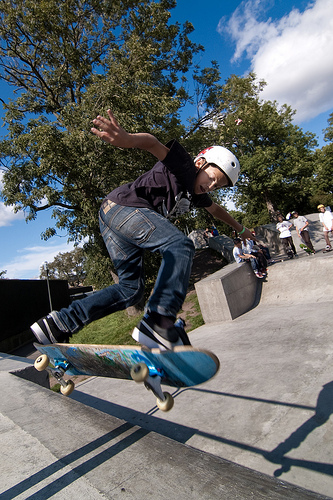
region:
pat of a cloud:
[266, 42, 302, 95]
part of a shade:
[86, 434, 138, 486]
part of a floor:
[133, 454, 167, 494]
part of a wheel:
[136, 377, 184, 445]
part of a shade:
[205, 414, 234, 464]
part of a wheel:
[159, 382, 181, 399]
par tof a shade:
[121, 427, 151, 456]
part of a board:
[158, 362, 169, 380]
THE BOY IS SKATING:
[26, 90, 273, 413]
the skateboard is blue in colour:
[28, 327, 212, 406]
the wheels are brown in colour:
[116, 357, 151, 387]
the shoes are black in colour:
[32, 301, 71, 352]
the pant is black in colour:
[102, 218, 188, 298]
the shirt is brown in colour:
[134, 162, 177, 198]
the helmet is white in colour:
[198, 134, 242, 203]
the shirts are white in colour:
[272, 218, 307, 232]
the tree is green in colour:
[42, 65, 90, 123]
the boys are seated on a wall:
[225, 237, 281, 268]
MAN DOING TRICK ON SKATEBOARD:
[103, 121, 253, 381]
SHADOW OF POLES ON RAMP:
[40, 412, 181, 479]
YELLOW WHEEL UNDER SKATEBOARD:
[129, 358, 151, 379]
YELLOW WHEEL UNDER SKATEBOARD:
[158, 391, 177, 410]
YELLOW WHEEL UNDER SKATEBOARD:
[35, 354, 44, 372]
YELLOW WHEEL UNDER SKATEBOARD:
[56, 377, 83, 402]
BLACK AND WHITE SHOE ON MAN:
[128, 307, 202, 362]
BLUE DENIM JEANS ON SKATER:
[63, 270, 123, 334]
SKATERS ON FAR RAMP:
[264, 204, 329, 242]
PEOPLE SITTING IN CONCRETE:
[229, 234, 262, 270]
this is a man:
[42, 112, 270, 347]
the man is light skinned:
[118, 129, 146, 148]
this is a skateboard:
[74, 338, 138, 386]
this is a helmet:
[198, 149, 240, 168]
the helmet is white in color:
[216, 147, 230, 164]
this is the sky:
[204, 4, 320, 57]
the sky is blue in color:
[195, 8, 218, 42]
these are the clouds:
[267, 27, 303, 78]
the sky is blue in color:
[191, 6, 220, 19]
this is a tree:
[74, 19, 154, 92]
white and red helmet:
[194, 144, 240, 185]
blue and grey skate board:
[35, 342, 220, 386]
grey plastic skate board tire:
[130, 362, 147, 381]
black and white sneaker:
[132, 318, 191, 349]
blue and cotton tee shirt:
[102, 139, 211, 217]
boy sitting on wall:
[232, 238, 265, 281]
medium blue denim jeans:
[57, 198, 194, 335]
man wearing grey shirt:
[290, 209, 316, 256]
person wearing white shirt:
[317, 203, 332, 252]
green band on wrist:
[238, 225, 245, 235]